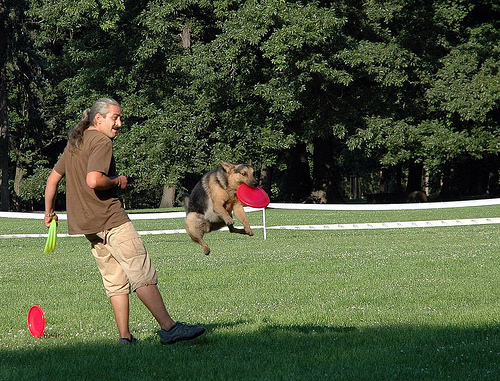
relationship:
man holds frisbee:
[71, 83, 155, 343] [33, 215, 75, 246]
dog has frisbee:
[162, 151, 281, 234] [232, 172, 261, 232]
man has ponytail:
[71, 83, 155, 343] [57, 105, 96, 143]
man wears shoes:
[71, 83, 155, 343] [119, 308, 203, 341]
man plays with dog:
[71, 83, 155, 343] [162, 151, 281, 234]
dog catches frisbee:
[162, 151, 281, 234] [232, 172, 261, 232]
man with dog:
[71, 83, 155, 343] [162, 151, 281, 234]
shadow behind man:
[39, 331, 492, 379] [71, 83, 155, 343]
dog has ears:
[162, 151, 281, 234] [219, 154, 263, 174]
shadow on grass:
[39, 331, 492, 379] [235, 291, 436, 378]